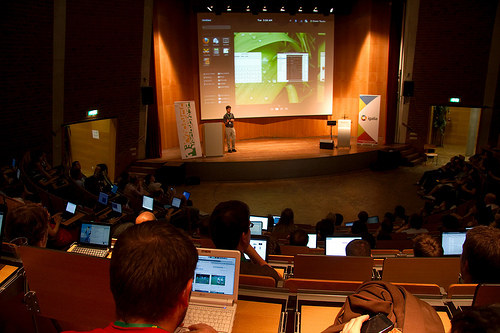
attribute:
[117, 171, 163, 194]
people — sitting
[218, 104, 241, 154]
man — standing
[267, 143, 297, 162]
stage — brown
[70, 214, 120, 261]
laptops — on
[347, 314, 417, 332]
mobil — black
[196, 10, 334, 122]
screen — very large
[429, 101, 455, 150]
plant — green